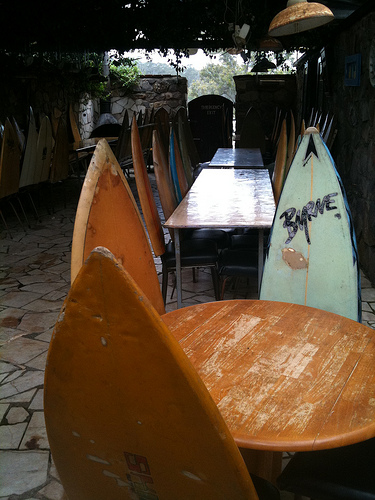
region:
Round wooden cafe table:
[147, 297, 374, 451]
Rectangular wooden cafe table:
[163, 165, 276, 231]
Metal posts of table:
[165, 229, 267, 305]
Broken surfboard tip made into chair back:
[253, 122, 361, 320]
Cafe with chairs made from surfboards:
[6, 101, 362, 499]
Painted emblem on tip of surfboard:
[299, 133, 322, 168]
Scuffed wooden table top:
[164, 297, 372, 445]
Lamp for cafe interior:
[266, 1, 337, 41]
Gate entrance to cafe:
[187, 92, 236, 163]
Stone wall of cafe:
[73, 75, 189, 158]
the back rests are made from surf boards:
[20, 124, 373, 496]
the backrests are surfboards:
[25, 110, 373, 498]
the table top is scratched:
[150, 295, 373, 449]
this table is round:
[137, 278, 373, 459]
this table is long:
[156, 160, 294, 246]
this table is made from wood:
[142, 276, 373, 453]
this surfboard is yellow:
[31, 242, 262, 499]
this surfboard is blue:
[229, 108, 367, 322]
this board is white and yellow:
[56, 131, 177, 312]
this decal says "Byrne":
[265, 188, 358, 257]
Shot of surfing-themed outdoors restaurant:
[1, 2, 371, 495]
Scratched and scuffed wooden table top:
[140, 300, 372, 448]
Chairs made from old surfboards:
[130, 113, 222, 297]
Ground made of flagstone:
[3, 233, 65, 313]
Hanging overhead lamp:
[266, 2, 332, 39]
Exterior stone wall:
[112, 73, 180, 113]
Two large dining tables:
[165, 146, 275, 301]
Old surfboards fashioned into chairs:
[41, 138, 256, 498]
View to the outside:
[108, 49, 293, 74]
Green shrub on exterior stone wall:
[107, 56, 138, 86]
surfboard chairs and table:
[46, 133, 370, 499]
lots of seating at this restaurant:
[2, 85, 373, 454]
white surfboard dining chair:
[274, 125, 362, 325]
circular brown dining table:
[158, 297, 373, 469]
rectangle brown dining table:
[166, 160, 277, 235]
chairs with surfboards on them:
[126, 119, 231, 301]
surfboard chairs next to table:
[49, 125, 372, 499]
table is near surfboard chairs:
[67, 132, 361, 497]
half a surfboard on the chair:
[128, 118, 231, 302]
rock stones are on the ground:
[0, 202, 55, 364]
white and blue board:
[244, 149, 343, 319]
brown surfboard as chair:
[40, 174, 176, 356]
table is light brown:
[155, 285, 349, 475]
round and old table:
[170, 278, 338, 449]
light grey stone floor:
[5, 275, 60, 408]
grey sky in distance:
[102, 42, 258, 90]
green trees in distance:
[138, 60, 234, 91]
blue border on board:
[155, 112, 187, 215]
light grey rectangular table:
[196, 155, 274, 239]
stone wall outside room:
[98, 81, 190, 126]